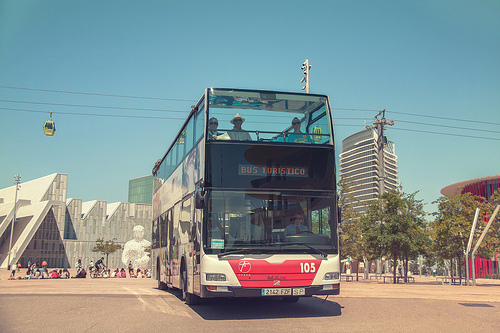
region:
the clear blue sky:
[385, 29, 470, 79]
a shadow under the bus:
[278, 299, 319, 319]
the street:
[354, 309, 393, 331]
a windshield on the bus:
[206, 198, 328, 241]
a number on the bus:
[288, 262, 318, 274]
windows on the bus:
[150, 218, 192, 242]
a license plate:
[261, 284, 295, 301]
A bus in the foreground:
[120, 72, 380, 322]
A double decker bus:
[128, 77, 379, 319]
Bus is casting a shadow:
[154, 268, 359, 332]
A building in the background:
[334, 113, 415, 245]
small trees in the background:
[340, 174, 498, 284]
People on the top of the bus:
[198, 95, 327, 145]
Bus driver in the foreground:
[277, 207, 318, 244]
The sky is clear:
[0, 3, 499, 221]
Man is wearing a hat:
[222, 109, 253, 149]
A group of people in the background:
[5, 254, 150, 284]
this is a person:
[206, 109, 219, 147]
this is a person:
[221, 110, 258, 138]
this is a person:
[287, 106, 308, 141]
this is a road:
[5, 227, 499, 324]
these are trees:
[349, 185, 466, 297]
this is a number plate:
[262, 288, 314, 297]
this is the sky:
[2, 3, 493, 179]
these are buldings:
[2, 157, 154, 279]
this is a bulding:
[336, 112, 423, 243]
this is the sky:
[40, 20, 146, 72]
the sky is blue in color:
[395, 46, 440, 91]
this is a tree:
[376, 185, 425, 289]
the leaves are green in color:
[387, 203, 416, 246]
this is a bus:
[160, 100, 332, 280]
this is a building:
[48, 165, 83, 250]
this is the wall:
[36, 224, 56, 260]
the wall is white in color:
[18, 178, 34, 208]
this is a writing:
[291, 254, 336, 284]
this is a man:
[229, 108, 246, 139]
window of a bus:
[212, 180, 274, 256]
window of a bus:
[276, 177, 343, 255]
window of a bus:
[206, 96, 270, 143]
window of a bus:
[280, 94, 336, 144]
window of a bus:
[188, 98, 213, 148]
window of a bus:
[173, 115, 191, 164]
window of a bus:
[156, 210, 173, 244]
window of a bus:
[150, 153, 164, 187]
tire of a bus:
[171, 256, 205, 308]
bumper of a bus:
[191, 244, 356, 313]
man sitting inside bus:
[216, 111, 251, 139]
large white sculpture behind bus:
[119, 222, 151, 272]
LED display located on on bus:
[238, 163, 306, 177]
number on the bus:
[280, 257, 333, 290]